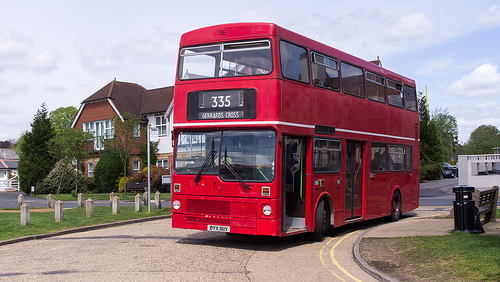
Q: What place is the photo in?
A: It is at the road.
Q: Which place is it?
A: It is a road.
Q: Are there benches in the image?
A: Yes, there is a bench.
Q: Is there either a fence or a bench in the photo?
A: Yes, there is a bench.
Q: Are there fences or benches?
A: Yes, there is a bench.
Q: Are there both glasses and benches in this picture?
A: No, there is a bench but no glasses.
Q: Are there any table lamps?
A: No, there are no table lamps.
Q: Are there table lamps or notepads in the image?
A: No, there are no table lamps or notepads.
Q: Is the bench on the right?
A: Yes, the bench is on the right of the image.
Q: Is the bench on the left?
A: No, the bench is on the right of the image.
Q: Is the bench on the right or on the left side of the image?
A: The bench is on the right of the image.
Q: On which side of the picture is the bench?
A: The bench is on the right of the image.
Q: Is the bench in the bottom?
A: Yes, the bench is in the bottom of the image.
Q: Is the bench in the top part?
A: No, the bench is in the bottom of the image.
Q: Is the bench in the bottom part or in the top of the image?
A: The bench is in the bottom of the image.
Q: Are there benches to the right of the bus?
A: Yes, there is a bench to the right of the bus.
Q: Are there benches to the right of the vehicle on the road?
A: Yes, there is a bench to the right of the bus.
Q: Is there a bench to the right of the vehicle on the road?
A: Yes, there is a bench to the right of the bus.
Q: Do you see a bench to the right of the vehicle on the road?
A: Yes, there is a bench to the right of the bus.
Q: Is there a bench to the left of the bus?
A: No, the bench is to the right of the bus.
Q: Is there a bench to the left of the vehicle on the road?
A: No, the bench is to the right of the bus.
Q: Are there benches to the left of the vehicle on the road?
A: No, the bench is to the right of the bus.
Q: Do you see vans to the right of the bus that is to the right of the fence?
A: No, there is a bench to the right of the bus.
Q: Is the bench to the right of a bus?
A: Yes, the bench is to the right of a bus.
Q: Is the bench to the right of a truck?
A: No, the bench is to the right of a bus.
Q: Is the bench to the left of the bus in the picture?
A: No, the bench is to the right of the bus.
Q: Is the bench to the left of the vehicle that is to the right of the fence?
A: No, the bench is to the right of the bus.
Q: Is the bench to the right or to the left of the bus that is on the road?
A: The bench is to the right of the bus.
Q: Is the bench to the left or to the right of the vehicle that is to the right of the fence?
A: The bench is to the right of the bus.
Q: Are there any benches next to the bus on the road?
A: Yes, there is a bench next to the bus.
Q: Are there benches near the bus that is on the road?
A: Yes, there is a bench near the bus.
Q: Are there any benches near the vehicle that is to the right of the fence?
A: Yes, there is a bench near the bus.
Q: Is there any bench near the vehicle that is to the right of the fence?
A: Yes, there is a bench near the bus.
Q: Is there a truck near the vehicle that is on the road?
A: No, there is a bench near the bus.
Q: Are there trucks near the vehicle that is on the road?
A: No, there is a bench near the bus.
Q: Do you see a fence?
A: Yes, there is a fence.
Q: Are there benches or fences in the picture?
A: Yes, there is a fence.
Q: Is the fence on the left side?
A: Yes, the fence is on the left of the image.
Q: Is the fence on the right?
A: No, the fence is on the left of the image.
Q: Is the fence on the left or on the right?
A: The fence is on the left of the image.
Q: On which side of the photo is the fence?
A: The fence is on the left of the image.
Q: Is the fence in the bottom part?
A: Yes, the fence is in the bottom of the image.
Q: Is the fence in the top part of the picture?
A: No, the fence is in the bottom of the image.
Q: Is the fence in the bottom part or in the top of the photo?
A: The fence is in the bottom of the image.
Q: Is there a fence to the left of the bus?
A: Yes, there is a fence to the left of the bus.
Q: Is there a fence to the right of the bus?
A: No, the fence is to the left of the bus.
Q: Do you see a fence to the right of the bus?
A: No, the fence is to the left of the bus.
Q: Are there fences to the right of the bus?
A: No, the fence is to the left of the bus.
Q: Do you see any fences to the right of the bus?
A: No, the fence is to the left of the bus.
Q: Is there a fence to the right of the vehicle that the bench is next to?
A: No, the fence is to the left of the bus.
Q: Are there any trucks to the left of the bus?
A: No, there is a fence to the left of the bus.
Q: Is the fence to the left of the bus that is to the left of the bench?
A: Yes, the fence is to the left of the bus.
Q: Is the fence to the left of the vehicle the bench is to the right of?
A: Yes, the fence is to the left of the bus.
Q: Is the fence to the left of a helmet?
A: No, the fence is to the left of the bus.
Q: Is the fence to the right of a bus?
A: No, the fence is to the left of a bus.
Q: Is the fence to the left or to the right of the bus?
A: The fence is to the left of the bus.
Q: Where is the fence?
A: The fence is on the road.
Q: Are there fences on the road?
A: Yes, there is a fence on the road.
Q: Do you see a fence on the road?
A: Yes, there is a fence on the road.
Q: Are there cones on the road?
A: No, there is a fence on the road.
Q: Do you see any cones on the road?
A: No, there is a fence on the road.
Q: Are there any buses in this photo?
A: Yes, there is a bus.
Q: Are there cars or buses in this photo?
A: Yes, there is a bus.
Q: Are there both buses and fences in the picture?
A: Yes, there are both a bus and a fence.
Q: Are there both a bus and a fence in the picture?
A: Yes, there are both a bus and a fence.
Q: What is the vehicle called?
A: The vehicle is a bus.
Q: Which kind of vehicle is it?
A: The vehicle is a bus.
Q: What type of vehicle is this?
A: This is a bus.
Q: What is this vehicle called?
A: This is a bus.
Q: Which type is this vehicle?
A: This is a bus.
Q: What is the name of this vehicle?
A: This is a bus.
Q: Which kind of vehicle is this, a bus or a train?
A: This is a bus.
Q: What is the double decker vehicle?
A: The vehicle is a bus.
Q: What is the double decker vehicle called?
A: The vehicle is a bus.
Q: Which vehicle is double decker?
A: The vehicle is a bus.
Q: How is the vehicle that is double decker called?
A: The vehicle is a bus.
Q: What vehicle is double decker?
A: The vehicle is a bus.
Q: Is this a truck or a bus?
A: This is a bus.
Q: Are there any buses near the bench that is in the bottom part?
A: Yes, there is a bus near the bench.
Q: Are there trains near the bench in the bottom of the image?
A: No, there is a bus near the bench.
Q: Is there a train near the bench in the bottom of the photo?
A: No, there is a bus near the bench.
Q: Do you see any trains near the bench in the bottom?
A: No, there is a bus near the bench.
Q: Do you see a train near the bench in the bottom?
A: No, there is a bus near the bench.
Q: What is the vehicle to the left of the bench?
A: The vehicle is a bus.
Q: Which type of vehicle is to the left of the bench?
A: The vehicle is a bus.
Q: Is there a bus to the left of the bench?
A: Yes, there is a bus to the left of the bench.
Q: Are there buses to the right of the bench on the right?
A: No, the bus is to the left of the bench.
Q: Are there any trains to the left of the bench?
A: No, there is a bus to the left of the bench.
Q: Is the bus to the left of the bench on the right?
A: Yes, the bus is to the left of the bench.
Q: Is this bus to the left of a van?
A: No, the bus is to the left of the bench.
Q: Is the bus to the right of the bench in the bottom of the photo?
A: No, the bus is to the left of the bench.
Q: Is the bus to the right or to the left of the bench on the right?
A: The bus is to the left of the bench.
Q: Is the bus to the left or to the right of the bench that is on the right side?
A: The bus is to the left of the bench.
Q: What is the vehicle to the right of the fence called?
A: The vehicle is a bus.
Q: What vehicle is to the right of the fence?
A: The vehicle is a bus.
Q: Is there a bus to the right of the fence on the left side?
A: Yes, there is a bus to the right of the fence.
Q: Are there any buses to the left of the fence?
A: No, the bus is to the right of the fence.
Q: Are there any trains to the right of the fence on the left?
A: No, there is a bus to the right of the fence.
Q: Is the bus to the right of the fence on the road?
A: Yes, the bus is to the right of the fence.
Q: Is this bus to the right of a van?
A: No, the bus is to the right of the fence.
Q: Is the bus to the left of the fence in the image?
A: No, the bus is to the right of the fence.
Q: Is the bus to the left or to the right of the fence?
A: The bus is to the right of the fence.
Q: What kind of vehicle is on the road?
A: The vehicle is a bus.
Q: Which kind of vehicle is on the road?
A: The vehicle is a bus.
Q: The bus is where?
A: The bus is on the road.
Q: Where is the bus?
A: The bus is on the road.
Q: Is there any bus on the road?
A: Yes, there is a bus on the road.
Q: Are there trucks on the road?
A: No, there is a bus on the road.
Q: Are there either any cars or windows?
A: Yes, there is a window.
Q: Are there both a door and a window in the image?
A: Yes, there are both a window and a door.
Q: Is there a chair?
A: No, there are no chairs.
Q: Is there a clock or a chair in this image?
A: No, there are no chairs or clocks.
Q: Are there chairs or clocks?
A: No, there are no chairs or clocks.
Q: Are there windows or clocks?
A: Yes, there is a window.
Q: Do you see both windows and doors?
A: Yes, there are both a window and a door.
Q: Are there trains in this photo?
A: No, there are no trains.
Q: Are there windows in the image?
A: Yes, there is a window.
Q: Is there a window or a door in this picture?
A: Yes, there is a window.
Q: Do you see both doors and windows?
A: Yes, there are both a window and a door.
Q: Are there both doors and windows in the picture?
A: Yes, there are both a window and a door.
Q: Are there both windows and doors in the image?
A: Yes, there are both a window and a door.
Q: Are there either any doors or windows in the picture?
A: Yes, there is a window.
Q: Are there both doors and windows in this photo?
A: Yes, there are both a window and a door.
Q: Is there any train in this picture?
A: No, there are no trains.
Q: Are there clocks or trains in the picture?
A: No, there are no trains or clocks.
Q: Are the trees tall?
A: Yes, the trees are tall.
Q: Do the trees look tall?
A: Yes, the trees are tall.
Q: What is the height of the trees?
A: The trees are tall.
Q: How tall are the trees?
A: The trees are tall.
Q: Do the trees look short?
A: No, the trees are tall.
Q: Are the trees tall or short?
A: The trees are tall.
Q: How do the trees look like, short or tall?
A: The trees are tall.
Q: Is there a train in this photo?
A: No, there are no trains.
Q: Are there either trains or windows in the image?
A: Yes, there is a window.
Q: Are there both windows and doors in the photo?
A: Yes, there are both a window and doors.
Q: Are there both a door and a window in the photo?
A: Yes, there are both a window and a door.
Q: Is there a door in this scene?
A: Yes, there is a door.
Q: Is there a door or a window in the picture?
A: Yes, there is a door.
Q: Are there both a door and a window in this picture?
A: Yes, there are both a door and a window.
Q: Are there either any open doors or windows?
A: Yes, there is an open door.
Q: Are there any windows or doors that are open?
A: Yes, the door is open.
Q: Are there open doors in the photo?
A: Yes, there is an open door.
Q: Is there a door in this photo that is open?
A: Yes, there is a door that is open.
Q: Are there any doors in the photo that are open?
A: Yes, there is a door that is open.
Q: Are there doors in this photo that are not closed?
A: Yes, there is a open door.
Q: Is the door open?
A: Yes, the door is open.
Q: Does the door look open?
A: Yes, the door is open.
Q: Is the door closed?
A: No, the door is open.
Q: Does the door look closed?
A: No, the door is open.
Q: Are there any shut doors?
A: No, there is a door but it is open.